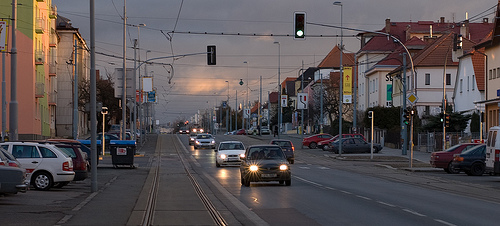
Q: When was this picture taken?
A: Evening.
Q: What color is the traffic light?
A: Green.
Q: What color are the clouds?
A: Grey.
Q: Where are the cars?
A: On the street.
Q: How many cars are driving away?
A: One.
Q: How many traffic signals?
A: Two.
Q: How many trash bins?
A: Two.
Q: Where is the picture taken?
A: In a city street.